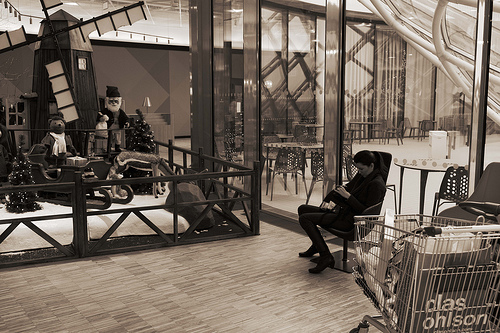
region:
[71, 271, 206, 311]
black lines on floor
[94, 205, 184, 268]
black design on railing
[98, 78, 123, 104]
large black hat on head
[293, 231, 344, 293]
woman wearing black boots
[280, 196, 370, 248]
skinny pants on woman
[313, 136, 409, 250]
sleek modern black chair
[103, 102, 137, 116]
white beard on man's face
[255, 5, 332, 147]
large clear glass in front of building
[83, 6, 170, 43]
large black and white windmill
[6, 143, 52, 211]
small green Christmas tree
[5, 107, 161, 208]
Two Christmas trees are seen.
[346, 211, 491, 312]
One trolley is seen.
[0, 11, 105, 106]
Wind power doll is seen.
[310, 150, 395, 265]
One woman is sitting in chair.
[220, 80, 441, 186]
Chair and tables are arranged behind the mirror.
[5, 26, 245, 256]
Christmas decoration is done.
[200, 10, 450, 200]
Light reflection is seen in mirror.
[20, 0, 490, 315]
Black and white picture.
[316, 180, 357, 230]
Lady is having handbag in her lap.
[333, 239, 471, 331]
trolley is in floor.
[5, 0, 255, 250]
A Christmas scene in a department store.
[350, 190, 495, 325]
A shopping cart.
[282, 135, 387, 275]
The woman is sitting in a chair.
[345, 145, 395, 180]
The woman's hair is in a ponytail.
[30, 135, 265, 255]
A wooden fence surrounds the Christmas scene.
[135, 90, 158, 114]
A lamp.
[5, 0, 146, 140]
A windmill.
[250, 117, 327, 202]
Tables and chairs behind the glass.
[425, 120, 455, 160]
A garbage bin.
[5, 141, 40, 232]
A small Christmas tree.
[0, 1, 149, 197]
windmill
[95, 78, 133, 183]
life-sized Santa doll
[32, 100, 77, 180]
teddy bear wearing a scarf and a sweater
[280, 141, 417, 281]
woman sitting in a chair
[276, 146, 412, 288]
woman sitting in a chair wearing dark clothing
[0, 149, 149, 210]
santa's sleigh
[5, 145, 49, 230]
miniature Christmas tree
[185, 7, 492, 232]
glass window panels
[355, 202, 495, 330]
shopping cart full of items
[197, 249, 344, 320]
wooden floor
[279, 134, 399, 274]
A woman sitting in a chair.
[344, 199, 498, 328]
Silver shopping cart.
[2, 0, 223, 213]
A display featuring Christmas items.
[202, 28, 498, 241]
a large glass enclosed room with tables and chairs inside.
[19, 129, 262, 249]
A fence enclosing a Christmas themed display.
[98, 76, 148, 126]
Santa in a Christmas themed display.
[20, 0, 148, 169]
A windmill on display.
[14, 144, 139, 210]
Santa's sleigh.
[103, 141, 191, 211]
A small fake reindeer.